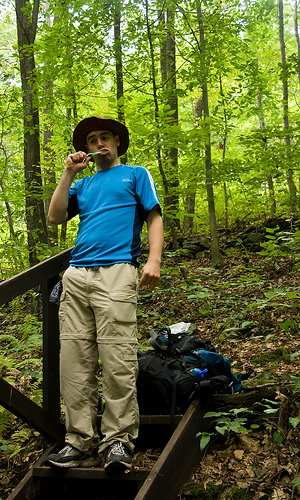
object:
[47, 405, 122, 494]
steps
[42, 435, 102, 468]
sneaker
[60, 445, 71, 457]
laces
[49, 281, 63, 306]
bandana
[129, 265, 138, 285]
pocket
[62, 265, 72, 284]
pocket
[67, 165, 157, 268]
t shirt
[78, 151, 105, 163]
toothbrush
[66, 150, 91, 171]
hand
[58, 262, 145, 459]
pants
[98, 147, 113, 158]
teeth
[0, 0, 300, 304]
forest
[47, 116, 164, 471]
boy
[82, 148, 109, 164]
brushing teeth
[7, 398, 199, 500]
rail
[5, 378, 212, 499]
stairs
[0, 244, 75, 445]
railing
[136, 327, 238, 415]
backpack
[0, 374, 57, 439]
brace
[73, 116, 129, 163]
hat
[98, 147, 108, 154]
mouth